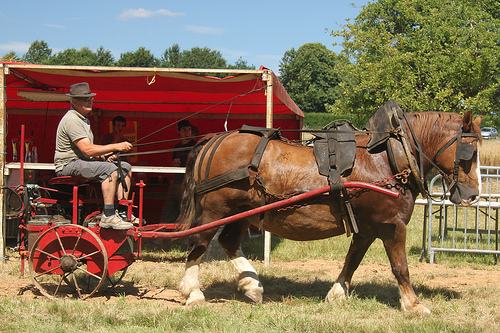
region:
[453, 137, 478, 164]
eye protection on the horse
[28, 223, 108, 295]
metal rimmed wheel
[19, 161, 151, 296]
a red horse cart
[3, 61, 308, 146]
a red tarp on the tent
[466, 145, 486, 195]
horse has a white nose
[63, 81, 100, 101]
hat on the man's head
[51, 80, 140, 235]
the man is steering the horse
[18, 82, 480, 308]
the horse is pulling a cart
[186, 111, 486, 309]
a brown horse with white feet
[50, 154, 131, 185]
the man is wearing shorts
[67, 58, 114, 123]
the head of a man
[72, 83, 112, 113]
the face of a man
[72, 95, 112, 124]
the chin of a man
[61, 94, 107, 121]
the face of a man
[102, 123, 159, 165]
the hand of a man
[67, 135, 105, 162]
the elbow of a man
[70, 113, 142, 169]
the arm of a man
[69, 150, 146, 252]
the legs of a man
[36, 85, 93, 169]
the shoulder of a man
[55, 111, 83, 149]
t shirt is grey in color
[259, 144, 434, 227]
horse is brown in color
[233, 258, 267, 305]
hoofs are white in color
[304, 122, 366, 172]
horse rope seat is black in color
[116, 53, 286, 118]
the tent is red in color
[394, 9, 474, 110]
plants are green in color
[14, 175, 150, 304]
a small red cart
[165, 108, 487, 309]
a large brown horse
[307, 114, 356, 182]
a black saddle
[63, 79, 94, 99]
a man's brown hat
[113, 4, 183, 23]
a small white cloud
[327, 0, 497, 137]
part of a large green tree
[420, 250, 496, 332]
green and brown grass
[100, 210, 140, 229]
a man's shoe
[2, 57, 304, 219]
a large red tent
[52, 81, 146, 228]
Man sitting on red cart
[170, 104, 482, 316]
brown horse dragging red cart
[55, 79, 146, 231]
Man wearing brown hat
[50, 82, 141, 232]
Man wearing gray shirt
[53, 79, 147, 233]
Man wearing gray shoes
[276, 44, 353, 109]
green tree is next to green tree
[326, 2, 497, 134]
green tree is next to green tree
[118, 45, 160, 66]
green tree is next to green tree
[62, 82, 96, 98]
Brimmed hat shading the man's head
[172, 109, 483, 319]
Horse pulling the red cart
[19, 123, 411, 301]
Red cart being pulled by the horse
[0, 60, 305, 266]
Tent providing shade for people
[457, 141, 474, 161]
Blinders on the horse's head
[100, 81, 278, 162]
Bull whip being held by the man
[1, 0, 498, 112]
Trees visible in the background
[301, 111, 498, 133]
Hedge in front of the trees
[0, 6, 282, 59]
Clouds in a mostly clear blue sky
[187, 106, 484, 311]
The horse pulling the carriage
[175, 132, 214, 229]
The brown tail of the horse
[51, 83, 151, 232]
The man on the carriage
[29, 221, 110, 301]
The wheel of the carriage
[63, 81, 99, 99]
The brown top hat on the man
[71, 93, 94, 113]
The face of the man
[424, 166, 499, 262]
the guard rail behind the horse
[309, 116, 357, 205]
The saddle on the back of the horse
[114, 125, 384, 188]
The reigns in the hands of the man